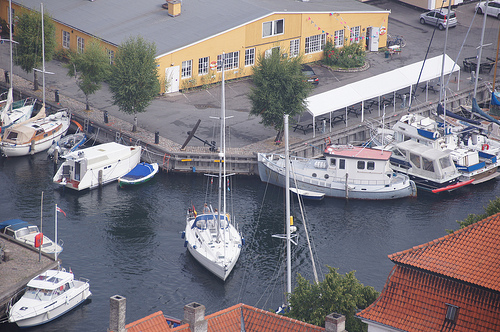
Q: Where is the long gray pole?
A: In a boat.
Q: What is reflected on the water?
A: The ship.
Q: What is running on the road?
A: A car.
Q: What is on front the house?
A: A tree.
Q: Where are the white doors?
A: In a building.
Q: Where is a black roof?
A: On a building.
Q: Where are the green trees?
A: On front a building.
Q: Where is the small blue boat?
A: Next to dock.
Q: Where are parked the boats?
A: In the marina.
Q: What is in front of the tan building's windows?
A: Large bushes.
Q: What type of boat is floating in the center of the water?
A: A sailboat.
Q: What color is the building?
A: Yellow.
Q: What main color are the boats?
A: White.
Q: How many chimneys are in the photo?
A: Four.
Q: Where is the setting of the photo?
A: A harbor.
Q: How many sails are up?
A: None.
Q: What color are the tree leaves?
A: Green.